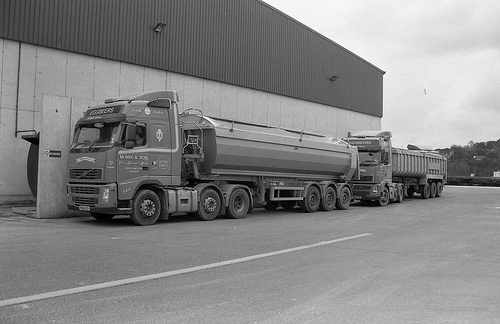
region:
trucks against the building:
[55, 86, 447, 217]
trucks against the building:
[67, 73, 452, 228]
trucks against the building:
[62, 84, 457, 230]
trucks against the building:
[57, 90, 452, 223]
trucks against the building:
[62, 80, 467, 231]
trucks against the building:
[64, 83, 440, 233]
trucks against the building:
[57, 69, 478, 235]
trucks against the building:
[76, 73, 466, 250]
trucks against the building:
[35, 75, 464, 253]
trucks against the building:
[28, 82, 455, 237]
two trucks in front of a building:
[40, 18, 465, 258]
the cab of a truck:
[71, 84, 181, 222]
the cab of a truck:
[345, 126, 394, 208]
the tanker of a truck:
[182, 102, 359, 184]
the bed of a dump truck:
[391, 143, 451, 196]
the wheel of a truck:
[128, 184, 160, 228]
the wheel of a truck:
[198, 187, 219, 218]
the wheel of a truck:
[230, 186, 251, 218]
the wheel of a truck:
[304, 183, 319, 212]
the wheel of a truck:
[321, 185, 336, 210]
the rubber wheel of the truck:
[134, 189, 163, 223]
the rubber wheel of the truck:
[197, 184, 221, 219]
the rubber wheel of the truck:
[229, 188, 249, 215]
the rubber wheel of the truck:
[305, 185, 320, 210]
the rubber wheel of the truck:
[323, 185, 334, 207]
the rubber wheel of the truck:
[337, 185, 352, 207]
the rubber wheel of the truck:
[377, 185, 390, 205]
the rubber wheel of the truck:
[396, 186, 403, 201]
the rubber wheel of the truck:
[422, 181, 430, 198]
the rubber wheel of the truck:
[430, 183, 437, 196]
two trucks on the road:
[66, 89, 458, 224]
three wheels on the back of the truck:
[301, 182, 358, 212]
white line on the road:
[1, 229, 376, 322]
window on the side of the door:
[128, 121, 152, 148]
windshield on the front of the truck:
[72, 122, 119, 146]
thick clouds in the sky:
[273, 0, 499, 147]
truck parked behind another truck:
[56, 70, 456, 228]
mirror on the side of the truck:
[380, 148, 389, 165]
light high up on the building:
[328, 70, 340, 81]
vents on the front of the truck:
[70, 165, 103, 203]